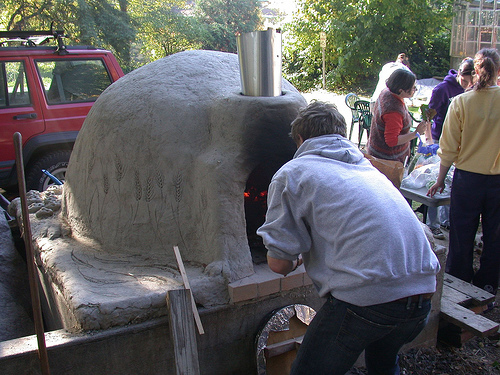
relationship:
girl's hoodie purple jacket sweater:
[426, 68, 463, 145] [438, 84, 500, 176]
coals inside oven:
[248, 177, 267, 203] [52, 7, 322, 277]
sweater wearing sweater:
[438, 84, 500, 176] [431, 79, 483, 183]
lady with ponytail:
[426, 53, 476, 149] [469, 45, 495, 90]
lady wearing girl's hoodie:
[426, 53, 468, 149] [426, 68, 463, 145]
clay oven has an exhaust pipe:
[63, 22, 296, 270] [230, 15, 285, 95]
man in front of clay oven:
[264, 102, 456, 371] [48, 25, 338, 270]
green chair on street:
[355, 96, 378, 128] [301, 84, 368, 134]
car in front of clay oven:
[2, 22, 123, 184] [41, 19, 363, 285]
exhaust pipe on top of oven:
[232, 25, 284, 97] [52, 7, 322, 277]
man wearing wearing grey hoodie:
[253, 132, 442, 375] [254, 134, 442, 308]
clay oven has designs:
[63, 22, 296, 270] [73, 144, 176, 295]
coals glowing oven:
[248, 179, 272, 213] [233, 171, 326, 274]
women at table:
[371, 62, 438, 197] [399, 153, 477, 230]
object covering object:
[246, 299, 323, 374] [246, 299, 323, 368]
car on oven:
[0, 28, 126, 199] [39, 42, 346, 299]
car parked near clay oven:
[0, 28, 126, 199] [7, 25, 351, 317]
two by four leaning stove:
[163, 281, 217, 373] [54, 13, 394, 300]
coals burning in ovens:
[248, 179, 272, 213] [76, 23, 381, 299]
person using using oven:
[264, 100, 473, 374] [46, 1, 312, 285]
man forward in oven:
[255, 102, 442, 371] [55, 19, 345, 282]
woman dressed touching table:
[429, 48, 499, 289] [393, 170, 463, 257]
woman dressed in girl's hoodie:
[424, 40, 495, 289] [426, 68, 463, 145]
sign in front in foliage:
[316, 28, 332, 87] [281, 4, 448, 88]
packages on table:
[399, 151, 460, 191] [398, 177, 457, 234]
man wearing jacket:
[264, 102, 456, 371] [268, 136, 442, 299]